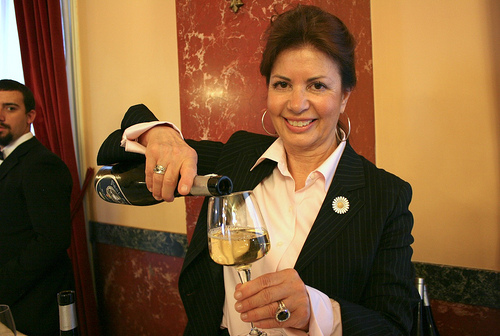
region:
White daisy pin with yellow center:
[332, 193, 347, 215]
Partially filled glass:
[207, 194, 267, 265]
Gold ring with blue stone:
[273, 300, 291, 322]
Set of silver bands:
[153, 161, 165, 176]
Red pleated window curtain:
[14, 3, 66, 81]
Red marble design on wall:
[186, 12, 245, 107]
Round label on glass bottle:
[93, 169, 130, 202]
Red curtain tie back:
[82, 164, 95, 194]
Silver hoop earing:
[257, 108, 269, 130]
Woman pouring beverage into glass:
[120, 25, 337, 326]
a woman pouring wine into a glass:
[97, 12, 409, 322]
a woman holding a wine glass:
[166, 16, 383, 307]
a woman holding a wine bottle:
[73, 30, 373, 280]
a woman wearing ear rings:
[236, 15, 368, 167]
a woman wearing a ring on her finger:
[110, 145, 184, 220]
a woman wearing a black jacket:
[261, 9, 367, 238]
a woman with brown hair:
[252, 12, 377, 97]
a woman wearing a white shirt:
[253, 30, 363, 265]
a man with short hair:
[2, 67, 44, 154]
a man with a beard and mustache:
[0, 76, 44, 154]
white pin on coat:
[325, 194, 355, 218]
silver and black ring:
[274, 292, 297, 329]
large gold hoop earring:
[332, 104, 353, 140]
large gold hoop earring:
[257, 99, 286, 142]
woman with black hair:
[87, 3, 423, 335]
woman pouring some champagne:
[76, 4, 421, 334]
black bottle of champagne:
[88, 155, 233, 210]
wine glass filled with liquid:
[198, 183, 283, 334]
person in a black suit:
[0, 78, 86, 334]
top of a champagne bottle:
[48, 284, 88, 334]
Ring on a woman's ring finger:
[151, 163, 166, 176]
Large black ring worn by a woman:
[274, 298, 289, 320]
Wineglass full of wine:
[206, 188, 271, 334]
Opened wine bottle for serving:
[92, 155, 233, 207]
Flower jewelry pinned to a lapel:
[331, 195, 348, 212]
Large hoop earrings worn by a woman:
[336, 112, 351, 142]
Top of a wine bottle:
[53, 288, 78, 335]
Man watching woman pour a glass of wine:
[0, 79, 76, 334]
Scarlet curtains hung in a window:
[12, 1, 103, 334]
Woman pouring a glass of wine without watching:
[89, 5, 411, 334]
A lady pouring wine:
[88, 1, 433, 334]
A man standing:
[2, 58, 86, 333]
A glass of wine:
[203, 187, 282, 334]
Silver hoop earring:
[327, 101, 359, 153]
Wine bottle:
[73, 157, 230, 212]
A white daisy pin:
[323, 183, 355, 223]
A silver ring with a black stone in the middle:
[261, 294, 294, 322]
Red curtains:
[16, 3, 94, 313]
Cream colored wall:
[375, 0, 499, 165]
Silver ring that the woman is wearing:
[150, 156, 168, 179]